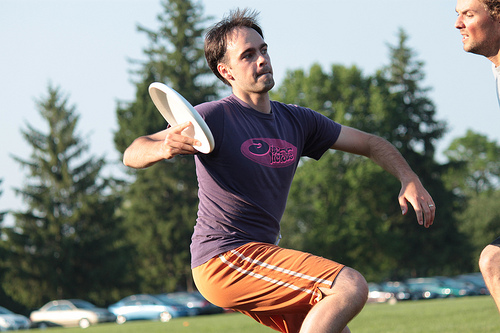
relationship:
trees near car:
[0, 0, 497, 315] [0, 267, 496, 333]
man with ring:
[116, 7, 441, 331] [427, 201, 437, 208]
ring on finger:
[427, 201, 437, 208] [425, 197, 437, 223]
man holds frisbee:
[116, 7, 441, 331] [145, 80, 216, 153]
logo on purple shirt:
[224, 122, 312, 187] [148, 96, 341, 270]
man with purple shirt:
[116, 7, 441, 331] [213, 101, 310, 249]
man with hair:
[116, 7, 441, 331] [203, 7, 263, 85]